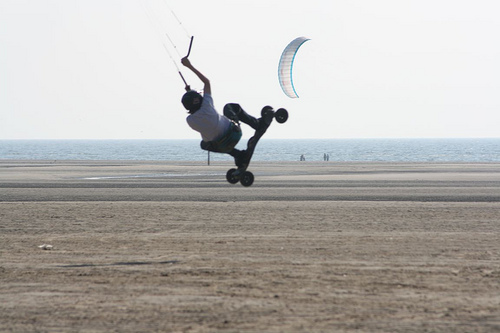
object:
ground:
[0, 160, 499, 332]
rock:
[33, 240, 58, 249]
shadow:
[55, 258, 177, 270]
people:
[296, 153, 312, 163]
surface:
[63, 126, 117, 138]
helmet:
[177, 92, 205, 111]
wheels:
[236, 170, 255, 187]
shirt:
[180, 94, 235, 145]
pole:
[181, 35, 195, 60]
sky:
[0, 0, 498, 140]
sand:
[0, 162, 499, 332]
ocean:
[0, 138, 499, 161]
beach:
[0, 160, 499, 332]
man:
[180, 55, 270, 168]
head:
[177, 85, 208, 116]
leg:
[221, 102, 259, 133]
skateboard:
[231, 102, 276, 174]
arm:
[186, 64, 213, 101]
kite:
[272, 35, 315, 101]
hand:
[181, 84, 196, 94]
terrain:
[0, 201, 499, 333]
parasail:
[273, 34, 313, 100]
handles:
[164, 70, 194, 95]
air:
[115, 29, 166, 84]